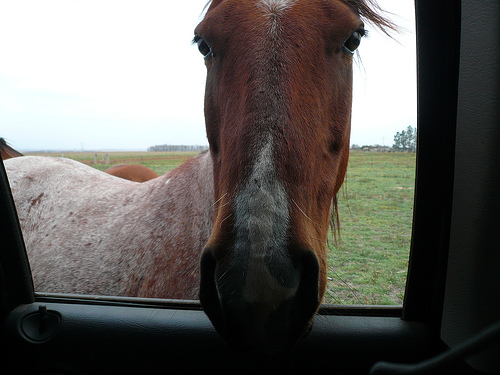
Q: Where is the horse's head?
A: In window.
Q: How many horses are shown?
A: 2.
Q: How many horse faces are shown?
A: 1.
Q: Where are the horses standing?
A: On grass.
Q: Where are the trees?
A: Background.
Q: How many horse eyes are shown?
A: 2.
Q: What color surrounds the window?
A: Black.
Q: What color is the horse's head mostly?
A: Brown.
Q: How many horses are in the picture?
A: 2.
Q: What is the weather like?
A: Sunny.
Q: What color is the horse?
A: Brown and white.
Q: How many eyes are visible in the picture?
A: 1.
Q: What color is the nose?
A: Black.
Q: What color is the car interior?
A: Black.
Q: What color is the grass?
A: Green.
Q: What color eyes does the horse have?
A: Brown.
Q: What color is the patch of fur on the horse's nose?
A: White.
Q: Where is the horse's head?
A: Inside of a car window.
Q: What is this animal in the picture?
A: A horse.